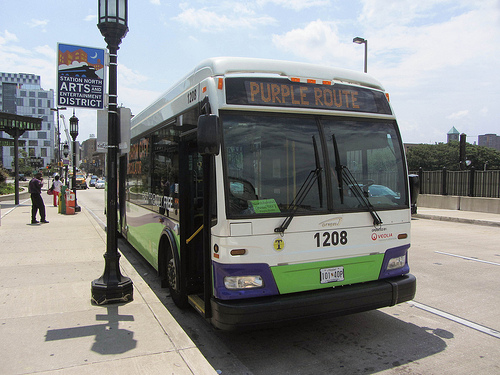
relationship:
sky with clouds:
[1, 2, 498, 62] [390, 10, 495, 127]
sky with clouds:
[1, 2, 498, 62] [185, 8, 337, 55]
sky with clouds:
[1, 2, 498, 62] [0, 29, 50, 74]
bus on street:
[104, 57, 416, 332] [88, 179, 498, 373]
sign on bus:
[219, 69, 398, 122] [120, 52, 430, 322]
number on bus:
[296, 229, 367, 253] [120, 52, 430, 322]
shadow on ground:
[142, 264, 466, 371] [15, 190, 207, 370]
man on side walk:
[22, 166, 51, 227] [2, 167, 92, 370]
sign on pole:
[52, 43, 107, 110] [87, 42, 134, 306]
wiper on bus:
[269, 133, 384, 231] [102, 52, 417, 335]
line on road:
[413, 294, 498, 352] [409, 246, 488, 371]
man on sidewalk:
[28, 173, 49, 224] [1, 201, 217, 373]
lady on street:
[48, 174, 63, 208] [19, 173, 89, 230]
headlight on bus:
[223, 274, 265, 290] [102, 52, 417, 335]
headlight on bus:
[388, 255, 407, 270] [102, 52, 417, 335]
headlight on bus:
[220, 270, 262, 290] [102, 52, 417, 335]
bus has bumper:
[104, 57, 416, 332] [215, 275, 420, 331]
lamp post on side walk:
[86, 6, 144, 332] [2, 167, 179, 370]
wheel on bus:
[166, 255, 178, 292] [102, 52, 417, 335]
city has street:
[2, 4, 495, 373] [88, 179, 498, 373]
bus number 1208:
[102, 52, 417, 335] [309, 223, 355, 253]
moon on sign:
[90, 51, 98, 59] [61, 45, 106, 108]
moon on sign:
[86, 45, 101, 63] [49, 38, 107, 113]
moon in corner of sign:
[90, 51, 98, 59] [49, 43, 122, 128]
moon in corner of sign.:
[90, 51, 98, 59] [58, 40, 108, 113]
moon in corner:
[90, 51, 98, 59] [85, 45, 103, 68]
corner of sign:
[85, 45, 103, 68] [55, 41, 108, 116]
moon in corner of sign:
[90, 51, 98, 59] [49, 42, 110, 108]